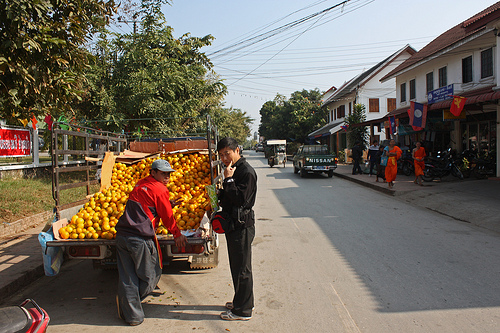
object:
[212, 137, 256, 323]
men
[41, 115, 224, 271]
truck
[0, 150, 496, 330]
street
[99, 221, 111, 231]
oranges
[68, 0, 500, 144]
sky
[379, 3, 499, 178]
building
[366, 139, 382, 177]
people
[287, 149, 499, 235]
sidewalk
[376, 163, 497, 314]
shadow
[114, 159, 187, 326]
man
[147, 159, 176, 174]
hat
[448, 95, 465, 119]
flag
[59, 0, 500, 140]
power lines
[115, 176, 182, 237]
top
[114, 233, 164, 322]
pants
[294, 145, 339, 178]
truck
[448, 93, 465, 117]
sign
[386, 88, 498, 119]
awning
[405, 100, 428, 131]
flags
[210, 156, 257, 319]
outfit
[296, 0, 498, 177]
buildings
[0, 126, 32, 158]
sign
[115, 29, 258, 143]
trees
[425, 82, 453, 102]
poster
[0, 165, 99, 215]
grass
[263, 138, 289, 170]
bicycle cart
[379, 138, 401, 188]
lady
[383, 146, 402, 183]
dress